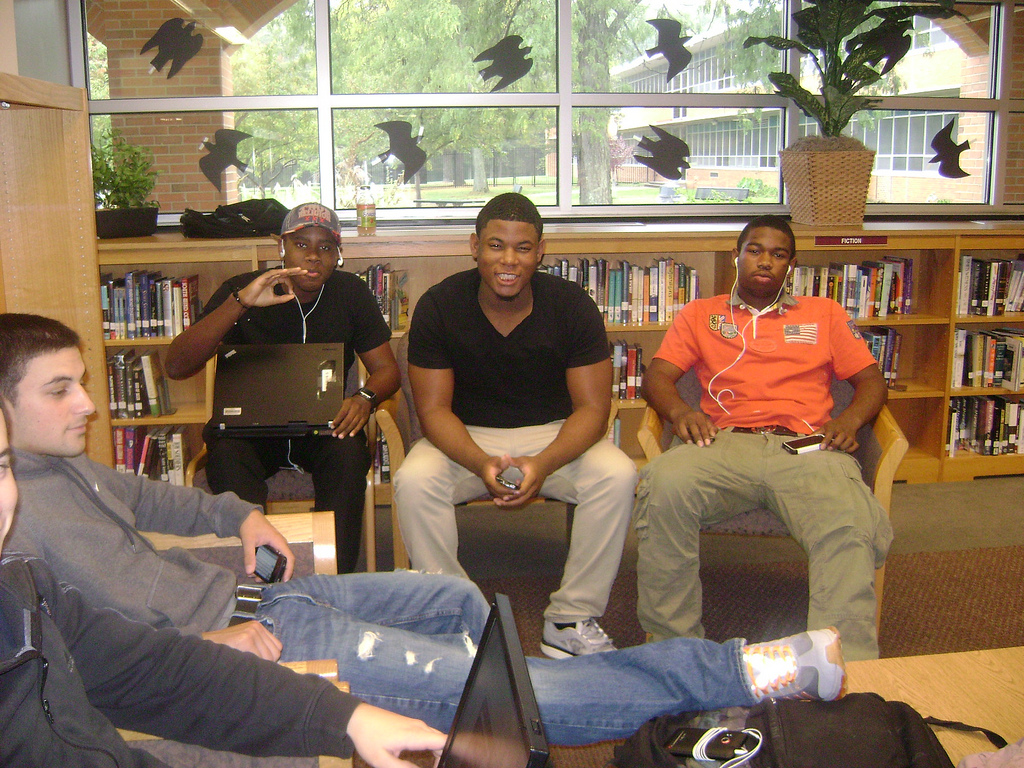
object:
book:
[600, 258, 609, 324]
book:
[614, 259, 628, 324]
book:
[646, 266, 658, 322]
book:
[664, 256, 674, 321]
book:
[126, 270, 138, 338]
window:
[103, 110, 316, 220]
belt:
[228, 581, 260, 626]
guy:
[628, 212, 893, 650]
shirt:
[403, 276, 600, 427]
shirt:
[204, 270, 382, 424]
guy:
[183, 200, 402, 499]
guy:
[385, 194, 630, 610]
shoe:
[737, 622, 842, 711]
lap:
[194, 429, 366, 523]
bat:
[139, 17, 204, 79]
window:
[83, 4, 316, 98]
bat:
[473, 35, 533, 93]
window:
[326, 1, 556, 94]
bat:
[643, 17, 692, 82]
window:
[570, 0, 781, 98]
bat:
[634, 124, 693, 180]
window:
[572, 108, 785, 204]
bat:
[928, 121, 972, 179]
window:
[803, 108, 994, 204]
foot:
[537, 613, 617, 665]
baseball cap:
[281, 202, 342, 238]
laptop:
[206, 344, 348, 437]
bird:
[370, 120, 425, 185]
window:
[334, 108, 558, 204]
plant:
[751, 4, 918, 137]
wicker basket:
[777, 138, 865, 232]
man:
[15, 310, 167, 610]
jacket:
[6, 456, 259, 618]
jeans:
[250, 571, 748, 735]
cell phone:
[254, 544, 289, 584]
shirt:
[659, 289, 868, 432]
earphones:
[706, 255, 818, 432]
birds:
[200, 128, 251, 194]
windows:
[804, 0, 993, 102]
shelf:
[95, 217, 1024, 477]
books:
[99, 256, 1023, 482]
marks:
[354, 630, 476, 673]